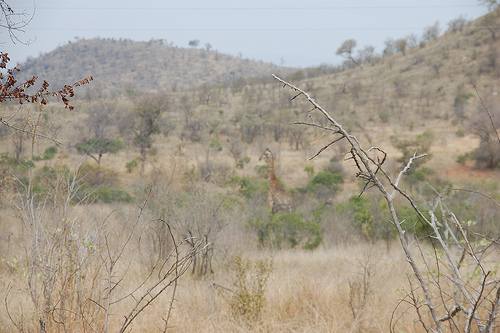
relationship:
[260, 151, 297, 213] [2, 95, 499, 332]
giraffe in a field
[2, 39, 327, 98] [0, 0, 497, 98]
hill in background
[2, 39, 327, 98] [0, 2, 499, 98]
hill in distance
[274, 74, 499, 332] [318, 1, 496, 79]
tree on a mound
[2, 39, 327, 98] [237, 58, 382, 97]
hill close to valley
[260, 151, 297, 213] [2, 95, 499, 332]
giraffe in field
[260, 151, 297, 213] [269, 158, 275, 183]
giraffe has a neck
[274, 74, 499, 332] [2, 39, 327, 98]
tree on a hill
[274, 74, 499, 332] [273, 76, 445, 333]
tree has a branch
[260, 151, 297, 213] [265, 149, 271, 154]
giraffe has a ear